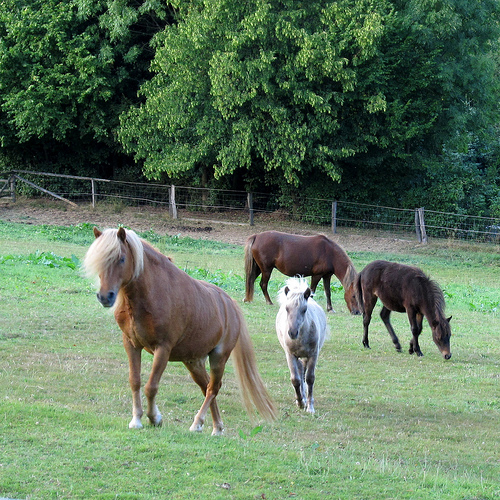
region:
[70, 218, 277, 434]
horse walking up a small hill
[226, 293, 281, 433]
brushed out horse's tail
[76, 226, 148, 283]
brushed out horse's mane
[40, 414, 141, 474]
green grass in a field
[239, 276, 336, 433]
white horse trotting up the small hill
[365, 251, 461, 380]
brown horse grazing in the field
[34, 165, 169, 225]
wire fence along the edge of the field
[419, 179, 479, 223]
trees behind the fence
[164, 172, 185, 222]
wooden fence post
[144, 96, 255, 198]
tree limbs hanging over the fence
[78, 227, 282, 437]
tan horse with long hair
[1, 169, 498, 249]
wire fence with wood poles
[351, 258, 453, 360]
dark brown horse grazing in grassy field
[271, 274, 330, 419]
white horse trotting in field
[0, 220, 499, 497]
green grassy field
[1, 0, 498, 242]
thick trees and bush in background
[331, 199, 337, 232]
wooden fence post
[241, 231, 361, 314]
beautiful brown horse grazing in field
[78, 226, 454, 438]
four horses in grassy field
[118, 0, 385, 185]
large green and bushy tree behind fence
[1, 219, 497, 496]
A green field in the foreground.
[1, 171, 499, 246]
A fence on the edge of the field.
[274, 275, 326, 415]
A white horse.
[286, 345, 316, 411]
Front legs of a white horse.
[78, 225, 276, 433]
A light brown horse.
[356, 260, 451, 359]
A dark brown horse.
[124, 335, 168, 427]
Front legs of a light brown horse.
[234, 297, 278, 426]
A tail of a light brown horse.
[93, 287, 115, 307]
A nose of a light brown horse.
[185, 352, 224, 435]
Rear legs of a light brown horse.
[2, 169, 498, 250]
the low fence in front of the trees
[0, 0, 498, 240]
the trees behind the horses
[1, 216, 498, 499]
the grass under the horses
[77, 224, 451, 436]
the small group of horses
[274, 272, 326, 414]
the light colored horse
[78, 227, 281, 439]
the horse with blond hair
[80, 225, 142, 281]
the blond mane on the horse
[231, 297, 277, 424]
the blond tail on the horse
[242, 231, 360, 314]
the horse closest to the trees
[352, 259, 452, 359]
the darkest horse with its head down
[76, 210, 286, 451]
horse standing in a field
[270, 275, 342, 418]
horse standing in a field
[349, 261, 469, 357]
horse standing in a field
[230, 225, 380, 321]
horse standing in a field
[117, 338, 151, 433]
leg of a horse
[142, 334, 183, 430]
leg of a horse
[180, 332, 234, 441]
leg of a horse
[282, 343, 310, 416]
leg of a horse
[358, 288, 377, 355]
leg of a horse